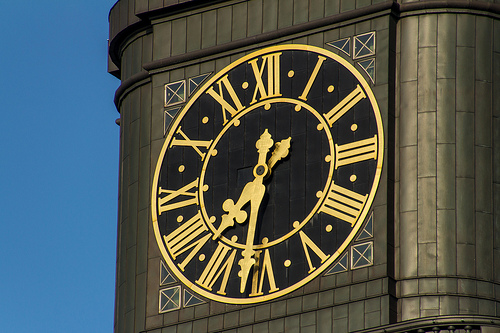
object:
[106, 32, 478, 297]
column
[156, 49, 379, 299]
background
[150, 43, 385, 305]
clock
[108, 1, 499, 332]
tower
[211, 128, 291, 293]
hands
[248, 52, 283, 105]
roman numerals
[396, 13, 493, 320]
bricks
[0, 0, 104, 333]
sky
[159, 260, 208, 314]
decorative corner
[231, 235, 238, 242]
circle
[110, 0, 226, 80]
shadows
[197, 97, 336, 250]
circle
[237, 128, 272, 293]
minute hand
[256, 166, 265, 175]
screw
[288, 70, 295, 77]
gold dot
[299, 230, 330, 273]
roman numerals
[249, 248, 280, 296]
number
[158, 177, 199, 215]
number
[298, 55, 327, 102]
number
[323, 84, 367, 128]
number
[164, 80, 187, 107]
square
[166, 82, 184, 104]
x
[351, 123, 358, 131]
dot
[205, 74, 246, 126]
object